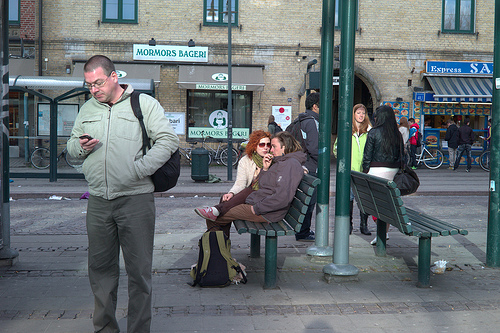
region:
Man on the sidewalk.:
[44, 37, 218, 327]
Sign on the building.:
[112, 27, 327, 82]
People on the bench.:
[174, 113, 374, 323]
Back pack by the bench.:
[165, 199, 280, 321]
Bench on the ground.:
[246, 157, 317, 304]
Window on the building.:
[174, 69, 263, 166]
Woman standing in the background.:
[311, 86, 428, 240]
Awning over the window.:
[413, 54, 494, 131]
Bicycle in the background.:
[26, 115, 96, 184]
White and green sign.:
[130, 35, 228, 85]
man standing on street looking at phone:
[58, 45, 183, 327]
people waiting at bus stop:
[28, 13, 438, 330]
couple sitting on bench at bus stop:
[188, 103, 318, 286]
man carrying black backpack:
[53, 48, 190, 332]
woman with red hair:
[220, 118, 270, 203]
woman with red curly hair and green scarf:
[216, 115, 271, 208]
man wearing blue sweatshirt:
[261, 128, 333, 242]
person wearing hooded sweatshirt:
[268, 126, 315, 226]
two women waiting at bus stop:
[351, 98, 427, 261]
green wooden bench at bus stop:
[351, 158, 471, 298]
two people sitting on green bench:
[190, 119, 315, 283]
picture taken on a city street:
[12, 11, 490, 326]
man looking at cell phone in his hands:
[59, 38, 180, 328]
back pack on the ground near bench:
[175, 215, 248, 290]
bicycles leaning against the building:
[29, 123, 248, 170]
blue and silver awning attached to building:
[430, 71, 493, 100]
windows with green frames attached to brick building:
[90, 0, 252, 30]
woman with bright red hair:
[239, 126, 277, 170]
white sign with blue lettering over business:
[130, 36, 214, 66]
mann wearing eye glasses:
[66, 55, 131, 114]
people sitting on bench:
[185, 126, 305, 228]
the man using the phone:
[50, 50, 205, 327]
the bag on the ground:
[185, 225, 250, 290]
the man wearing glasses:
[61, 55, 125, 112]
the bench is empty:
[334, 159, 471, 278]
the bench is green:
[347, 163, 462, 286]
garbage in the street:
[41, 192, 76, 212]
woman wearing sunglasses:
[227, 132, 281, 163]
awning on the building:
[420, 75, 497, 102]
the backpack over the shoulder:
[122, 85, 194, 199]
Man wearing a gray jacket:
[61, 55, 181, 329]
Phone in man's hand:
[71, 129, 106, 160]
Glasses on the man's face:
[79, 75, 109, 90]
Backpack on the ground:
[181, 221, 250, 292]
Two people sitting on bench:
[204, 125, 316, 265]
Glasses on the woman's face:
[255, 137, 274, 153]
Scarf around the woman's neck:
[245, 148, 270, 172]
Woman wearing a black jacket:
[363, 105, 419, 255]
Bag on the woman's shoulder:
[383, 130, 424, 191]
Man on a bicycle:
[392, 111, 446, 175]